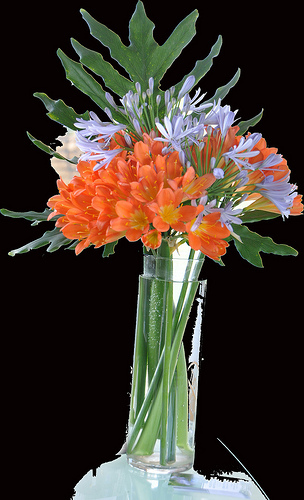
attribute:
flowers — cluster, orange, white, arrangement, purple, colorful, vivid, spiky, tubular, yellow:
[34, 67, 303, 268]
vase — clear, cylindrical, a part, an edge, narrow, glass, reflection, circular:
[119, 268, 207, 483]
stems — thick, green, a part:
[146, 242, 165, 394]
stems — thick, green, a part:
[160, 257, 174, 470]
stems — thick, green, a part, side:
[115, 240, 197, 456]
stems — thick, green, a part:
[178, 345, 190, 456]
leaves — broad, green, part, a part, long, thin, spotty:
[1, 4, 301, 278]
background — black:
[2, 1, 304, 500]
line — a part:
[135, 269, 207, 288]